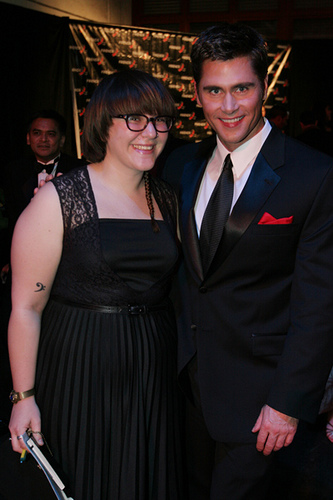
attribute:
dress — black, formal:
[32, 168, 180, 500]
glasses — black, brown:
[109, 111, 174, 131]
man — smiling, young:
[164, 24, 331, 499]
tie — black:
[194, 154, 234, 279]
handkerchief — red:
[258, 214, 295, 228]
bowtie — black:
[35, 160, 56, 175]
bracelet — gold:
[9, 385, 36, 408]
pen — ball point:
[20, 448, 28, 466]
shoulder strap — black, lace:
[48, 164, 102, 228]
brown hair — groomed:
[191, 21, 269, 96]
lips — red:
[218, 114, 247, 128]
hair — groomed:
[187, 24, 269, 91]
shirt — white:
[190, 114, 275, 244]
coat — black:
[160, 125, 332, 443]